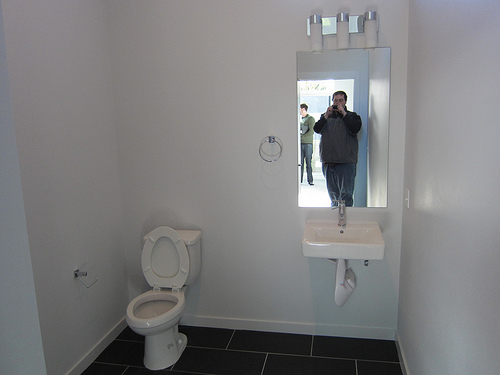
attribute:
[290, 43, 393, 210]
mirror — bathroom, pictured, tall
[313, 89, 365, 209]
person — picturing, taking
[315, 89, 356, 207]
man — picturing, photographing, thin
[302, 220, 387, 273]
sink — white, small, clean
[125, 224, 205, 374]
toilet — white, ceramic, clean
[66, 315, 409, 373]
tile — black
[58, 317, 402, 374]
tiles — black, dark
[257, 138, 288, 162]
holder — silver, circular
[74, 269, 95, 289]
paperholder — silver, roll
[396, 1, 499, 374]
wall — white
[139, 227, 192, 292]
seat — up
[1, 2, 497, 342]
walls — painted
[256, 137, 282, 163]
rack — empty